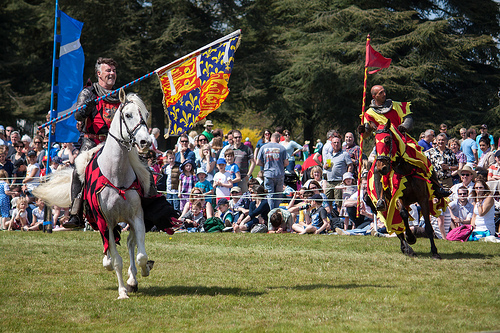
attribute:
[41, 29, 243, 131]
flag — multicolored, red, yellow, blue, gray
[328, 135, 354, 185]
person — watching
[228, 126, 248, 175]
person — watching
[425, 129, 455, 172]
person — watching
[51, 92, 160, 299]
horse — white, in motion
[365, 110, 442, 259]
horse — brown, in motion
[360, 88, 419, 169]
man — bald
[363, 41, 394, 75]
flag — red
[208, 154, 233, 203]
girl — little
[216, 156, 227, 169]
hat — blue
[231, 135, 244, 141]
sunglasses — dark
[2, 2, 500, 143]
trees — tall, green, full, pine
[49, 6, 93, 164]
flag — blue, tall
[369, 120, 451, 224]
gear — red, yellow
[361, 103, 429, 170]
costume — yellow, red, black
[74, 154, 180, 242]
costume — diamond pattern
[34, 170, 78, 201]
tail — in motion